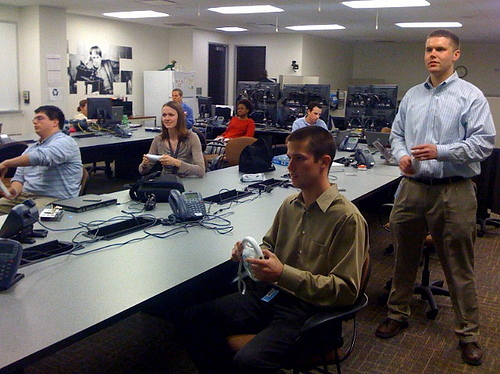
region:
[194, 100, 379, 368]
this is a person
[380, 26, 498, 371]
this is a person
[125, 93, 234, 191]
this is a person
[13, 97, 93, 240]
this is a person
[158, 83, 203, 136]
this is a person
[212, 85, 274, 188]
this is a person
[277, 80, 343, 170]
this is a person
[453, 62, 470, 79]
a round clock hanging on a wall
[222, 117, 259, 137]
a woman wearing a red shirt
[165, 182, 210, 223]
a telephone on a table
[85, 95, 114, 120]
a computer monitor on a table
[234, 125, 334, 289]
a young man holding a game controller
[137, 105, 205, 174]
a young woman holding a game controller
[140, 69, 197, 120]
a white refrigerator in a corner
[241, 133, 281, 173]
a black bag on a table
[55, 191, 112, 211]
a laptop computer on a table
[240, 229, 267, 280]
a white game controller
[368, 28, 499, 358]
standing man wearing blue shirt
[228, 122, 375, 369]
man wearing tan button down shirt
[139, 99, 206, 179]
woman with elbow on table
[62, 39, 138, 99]
black and white picture of man on wall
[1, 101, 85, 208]
man wearing blue shirt sitting down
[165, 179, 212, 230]
telephone next to man in tan shirt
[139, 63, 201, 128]
white refrigerator with freezer on top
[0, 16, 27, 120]
white dry erase board on wall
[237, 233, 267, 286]
white circle object held by man in tan shirt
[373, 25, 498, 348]
standing man wearing blue shirt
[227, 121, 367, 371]
man wearing tan button down shirt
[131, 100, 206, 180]
woman with elbow on table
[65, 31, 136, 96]
black and white picture of man on wall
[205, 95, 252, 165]
woman in red shirt sitting in chair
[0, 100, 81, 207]
man wearing blue shirt sitting down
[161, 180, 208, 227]
telephone next to man in tan shirt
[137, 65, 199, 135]
white refrigerator with freezer on top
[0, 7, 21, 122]
white dry erase board on wall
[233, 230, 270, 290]
white circle object held by man in tan shirt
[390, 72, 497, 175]
a blue and white striped shirt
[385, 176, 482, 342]
a pair of brown pleated pants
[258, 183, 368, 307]
a light green long sleeved shirt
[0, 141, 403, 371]
a long conference table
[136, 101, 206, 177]
a woman playing a video game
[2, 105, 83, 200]
a man playing a video game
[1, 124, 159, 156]
a long conference table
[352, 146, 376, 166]
a black telephone set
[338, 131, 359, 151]
a black telephone set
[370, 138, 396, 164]
an open laptop computer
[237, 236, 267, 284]
a Wii video game controller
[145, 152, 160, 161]
a Wii video game controller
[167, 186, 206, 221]
a telephone handset